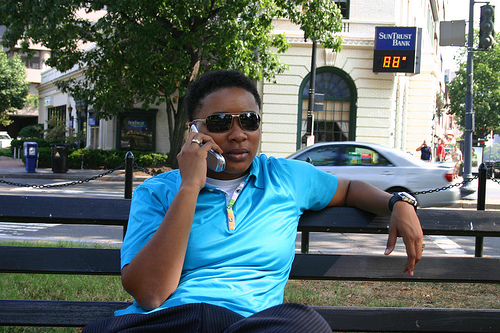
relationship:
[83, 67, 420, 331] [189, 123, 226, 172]
man on phone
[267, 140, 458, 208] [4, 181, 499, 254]
car on street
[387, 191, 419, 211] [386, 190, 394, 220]
watch with band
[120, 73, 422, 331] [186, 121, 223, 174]
man talking on phone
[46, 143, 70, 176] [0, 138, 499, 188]
garbage can on sidewalk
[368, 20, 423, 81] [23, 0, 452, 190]
sign on building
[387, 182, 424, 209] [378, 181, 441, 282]
watch on wrist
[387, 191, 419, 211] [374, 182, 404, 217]
watch with a wristband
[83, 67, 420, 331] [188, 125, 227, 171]
man talking on phone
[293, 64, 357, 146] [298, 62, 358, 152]
window with frame